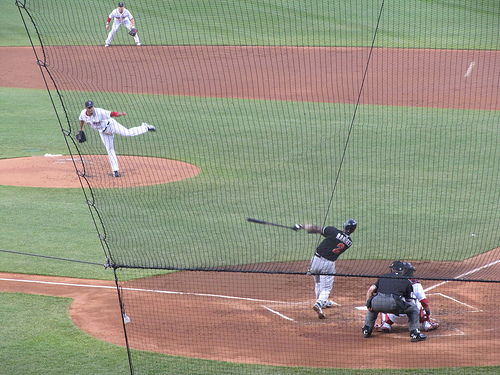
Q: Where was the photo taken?
A: It was taken at the field.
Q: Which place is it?
A: It is a field.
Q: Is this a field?
A: Yes, it is a field.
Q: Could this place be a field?
A: Yes, it is a field.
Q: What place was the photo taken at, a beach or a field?
A: It was taken at a field.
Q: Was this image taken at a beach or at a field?
A: It was taken at a field.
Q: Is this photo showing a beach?
A: No, the picture is showing a field.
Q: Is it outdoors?
A: Yes, it is outdoors.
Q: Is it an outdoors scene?
A: Yes, it is outdoors.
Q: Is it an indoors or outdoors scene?
A: It is outdoors.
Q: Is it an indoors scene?
A: No, it is outdoors.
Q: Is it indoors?
A: No, it is outdoors.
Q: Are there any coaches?
A: No, there are no coaches.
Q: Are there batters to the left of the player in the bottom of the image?
A: Yes, there is a batter to the left of the player.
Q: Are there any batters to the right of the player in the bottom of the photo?
A: No, the batter is to the left of the player.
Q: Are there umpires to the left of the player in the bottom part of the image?
A: No, there is a batter to the left of the player.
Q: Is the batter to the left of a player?
A: Yes, the batter is to the left of a player.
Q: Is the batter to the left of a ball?
A: No, the batter is to the left of a player.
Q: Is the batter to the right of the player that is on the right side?
A: No, the batter is to the left of the player.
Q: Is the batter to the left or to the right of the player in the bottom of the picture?
A: The batter is to the left of the player.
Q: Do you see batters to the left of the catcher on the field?
A: Yes, there is a batter to the left of the catcher.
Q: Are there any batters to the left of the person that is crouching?
A: Yes, there is a batter to the left of the catcher.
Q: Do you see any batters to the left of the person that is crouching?
A: Yes, there is a batter to the left of the catcher.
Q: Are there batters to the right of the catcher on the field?
A: No, the batter is to the left of the catcher.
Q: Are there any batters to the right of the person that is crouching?
A: No, the batter is to the left of the catcher.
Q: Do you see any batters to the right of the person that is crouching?
A: No, the batter is to the left of the catcher.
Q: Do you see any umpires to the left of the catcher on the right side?
A: No, there is a batter to the left of the catcher.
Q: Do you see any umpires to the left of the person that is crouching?
A: No, there is a batter to the left of the catcher.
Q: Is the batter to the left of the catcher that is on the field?
A: Yes, the batter is to the left of the catcher.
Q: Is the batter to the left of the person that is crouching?
A: Yes, the batter is to the left of the catcher.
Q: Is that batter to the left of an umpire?
A: No, the batter is to the left of the catcher.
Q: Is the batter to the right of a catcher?
A: No, the batter is to the left of a catcher.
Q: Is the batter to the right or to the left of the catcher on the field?
A: The batter is to the left of the catcher.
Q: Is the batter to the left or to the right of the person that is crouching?
A: The batter is to the left of the catcher.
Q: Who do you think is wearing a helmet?
A: The batter is wearing a helmet.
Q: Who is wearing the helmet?
A: The batter is wearing a helmet.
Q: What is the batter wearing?
A: The batter is wearing a helmet.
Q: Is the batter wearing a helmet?
A: Yes, the batter is wearing a helmet.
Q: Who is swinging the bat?
A: The batter is swinging the bat.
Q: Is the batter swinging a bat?
A: Yes, the batter is swinging a bat.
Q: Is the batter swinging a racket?
A: No, the batter is swinging a bat.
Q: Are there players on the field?
A: Yes, there is a player on the field.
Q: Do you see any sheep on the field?
A: No, there is a player on the field.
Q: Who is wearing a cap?
A: The player is wearing a cap.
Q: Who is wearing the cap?
A: The player is wearing a cap.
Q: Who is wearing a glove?
A: The player is wearing a glove.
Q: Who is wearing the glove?
A: The player is wearing a glove.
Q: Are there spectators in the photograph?
A: No, there are no spectators.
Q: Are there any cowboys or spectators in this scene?
A: No, there are no spectators or cowboys.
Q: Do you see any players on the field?
A: Yes, there is a player on the field.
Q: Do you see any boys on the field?
A: No, there is a player on the field.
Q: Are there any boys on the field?
A: No, there is a player on the field.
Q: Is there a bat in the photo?
A: Yes, there is a bat.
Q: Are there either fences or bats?
A: Yes, there is a bat.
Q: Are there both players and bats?
A: Yes, there are both a bat and a player.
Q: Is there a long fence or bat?
A: Yes, there is a long bat.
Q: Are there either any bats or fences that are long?
A: Yes, the bat is long.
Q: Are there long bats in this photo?
A: Yes, there is a long bat.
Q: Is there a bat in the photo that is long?
A: Yes, there is a bat that is long.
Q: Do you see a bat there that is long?
A: Yes, there is a bat that is long.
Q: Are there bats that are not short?
A: Yes, there is a long bat.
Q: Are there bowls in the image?
A: No, there are no bowls.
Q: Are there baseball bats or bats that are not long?
A: No, there is a bat but it is long.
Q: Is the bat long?
A: Yes, the bat is long.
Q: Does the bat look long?
A: Yes, the bat is long.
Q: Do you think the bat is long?
A: Yes, the bat is long.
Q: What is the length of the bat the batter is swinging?
A: The bat is long.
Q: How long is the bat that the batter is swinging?
A: The bat is long.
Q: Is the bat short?
A: No, the bat is long.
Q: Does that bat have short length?
A: No, the bat is long.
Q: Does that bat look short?
A: No, the bat is long.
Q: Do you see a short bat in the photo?
A: No, there is a bat but it is long.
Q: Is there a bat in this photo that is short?
A: No, there is a bat but it is long.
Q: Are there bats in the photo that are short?
A: No, there is a bat but it is long.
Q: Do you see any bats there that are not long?
A: No, there is a bat but it is long.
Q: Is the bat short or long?
A: The bat is long.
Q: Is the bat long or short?
A: The bat is long.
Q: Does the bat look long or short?
A: The bat is long.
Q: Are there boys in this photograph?
A: No, there are no boys.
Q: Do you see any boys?
A: No, there are no boys.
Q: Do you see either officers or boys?
A: No, there are no boys or officers.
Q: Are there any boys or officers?
A: No, there are no boys or officers.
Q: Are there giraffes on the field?
A: No, there is a player on the field.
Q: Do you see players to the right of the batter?
A: Yes, there is a player to the right of the batter.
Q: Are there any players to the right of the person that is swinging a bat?
A: Yes, there is a player to the right of the batter.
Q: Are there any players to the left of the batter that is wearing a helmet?
A: No, the player is to the right of the batter.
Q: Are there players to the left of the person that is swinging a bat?
A: No, the player is to the right of the batter.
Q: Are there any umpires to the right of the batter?
A: No, there is a player to the right of the batter.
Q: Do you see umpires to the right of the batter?
A: No, there is a player to the right of the batter.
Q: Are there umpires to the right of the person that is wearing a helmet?
A: No, there is a player to the right of the batter.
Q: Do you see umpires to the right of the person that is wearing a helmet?
A: No, there is a player to the right of the batter.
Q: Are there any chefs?
A: No, there are no chefs.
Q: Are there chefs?
A: No, there are no chefs.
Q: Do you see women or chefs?
A: No, there are no chefs or women.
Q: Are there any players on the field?
A: Yes, there is a player on the field.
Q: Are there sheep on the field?
A: No, there is a player on the field.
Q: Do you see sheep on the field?
A: No, there is a player on the field.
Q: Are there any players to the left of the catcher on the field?
A: Yes, there is a player to the left of the catcher.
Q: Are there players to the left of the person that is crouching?
A: Yes, there is a player to the left of the catcher.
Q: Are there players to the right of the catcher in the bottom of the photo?
A: No, the player is to the left of the catcher.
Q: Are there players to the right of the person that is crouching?
A: No, the player is to the left of the catcher.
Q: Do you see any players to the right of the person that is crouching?
A: No, the player is to the left of the catcher.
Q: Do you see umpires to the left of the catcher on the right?
A: No, there is a player to the left of the catcher.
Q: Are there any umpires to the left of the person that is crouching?
A: No, there is a player to the left of the catcher.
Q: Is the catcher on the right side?
A: Yes, the catcher is on the right of the image.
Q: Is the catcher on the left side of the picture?
A: No, the catcher is on the right of the image.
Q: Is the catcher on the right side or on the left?
A: The catcher is on the right of the image.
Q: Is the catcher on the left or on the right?
A: The catcher is on the right of the image.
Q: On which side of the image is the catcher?
A: The catcher is on the right of the image.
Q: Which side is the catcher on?
A: The catcher is on the right of the image.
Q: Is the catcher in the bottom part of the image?
A: Yes, the catcher is in the bottom of the image.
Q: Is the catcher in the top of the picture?
A: No, the catcher is in the bottom of the image.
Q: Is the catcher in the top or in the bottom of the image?
A: The catcher is in the bottom of the image.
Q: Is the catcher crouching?
A: Yes, the catcher is crouching.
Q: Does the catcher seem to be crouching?
A: Yes, the catcher is crouching.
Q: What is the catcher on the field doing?
A: The catcher is crouching.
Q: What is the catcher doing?
A: The catcher is crouching.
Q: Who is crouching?
A: The catcher is crouching.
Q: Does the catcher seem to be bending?
A: No, the catcher is crouching.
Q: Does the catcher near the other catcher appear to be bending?
A: No, the catcher is crouching.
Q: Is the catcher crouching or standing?
A: The catcher is crouching.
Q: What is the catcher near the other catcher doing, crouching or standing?
A: The catcher is crouching.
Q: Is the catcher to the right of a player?
A: Yes, the catcher is to the right of a player.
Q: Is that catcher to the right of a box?
A: No, the catcher is to the right of a player.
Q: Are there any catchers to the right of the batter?
A: Yes, there is a catcher to the right of the batter.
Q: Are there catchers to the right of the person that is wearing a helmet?
A: Yes, there is a catcher to the right of the batter.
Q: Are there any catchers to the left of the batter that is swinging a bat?
A: No, the catcher is to the right of the batter.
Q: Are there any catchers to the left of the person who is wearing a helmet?
A: No, the catcher is to the right of the batter.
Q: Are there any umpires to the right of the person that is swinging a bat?
A: No, there is a catcher to the right of the batter.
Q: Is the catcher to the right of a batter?
A: Yes, the catcher is to the right of a batter.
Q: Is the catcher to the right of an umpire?
A: No, the catcher is to the right of a batter.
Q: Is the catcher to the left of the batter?
A: No, the catcher is to the right of the batter.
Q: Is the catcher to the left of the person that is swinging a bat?
A: No, the catcher is to the right of the batter.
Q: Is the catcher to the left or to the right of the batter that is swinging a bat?
A: The catcher is to the right of the batter.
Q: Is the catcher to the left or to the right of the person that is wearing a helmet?
A: The catcher is to the right of the batter.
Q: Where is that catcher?
A: The catcher is on the field.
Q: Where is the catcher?
A: The catcher is on the field.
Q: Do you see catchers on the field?
A: Yes, there is a catcher on the field.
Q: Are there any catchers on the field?
A: Yes, there is a catcher on the field.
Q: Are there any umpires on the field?
A: No, there is a catcher on the field.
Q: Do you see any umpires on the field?
A: No, there is a catcher on the field.